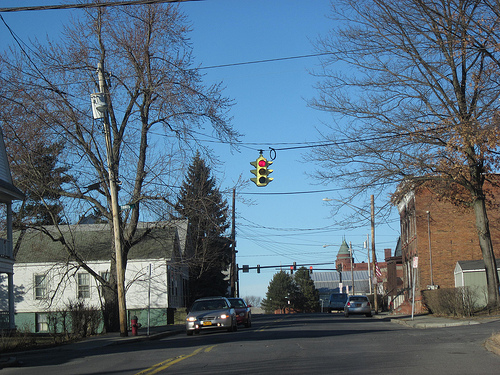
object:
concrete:
[0, 312, 497, 373]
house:
[0, 217, 189, 335]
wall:
[421, 191, 472, 244]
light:
[258, 159, 266, 167]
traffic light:
[290, 266, 295, 274]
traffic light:
[308, 266, 314, 274]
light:
[258, 176, 265, 183]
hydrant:
[131, 315, 142, 335]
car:
[185, 295, 237, 337]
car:
[226, 290, 253, 328]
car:
[343, 293, 374, 318]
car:
[328, 292, 349, 314]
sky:
[197, 15, 303, 48]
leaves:
[315, 40, 496, 188]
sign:
[412, 256, 418, 268]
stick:
[409, 270, 414, 320]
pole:
[101, 115, 131, 338]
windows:
[33, 272, 48, 301]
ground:
[391, 322, 429, 364]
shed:
[451, 255, 498, 317]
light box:
[249, 154, 274, 187]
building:
[453, 260, 500, 314]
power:
[85, 46, 136, 336]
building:
[0, 222, 185, 334]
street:
[1, 305, 498, 373]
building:
[389, 171, 499, 313]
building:
[336, 232, 388, 270]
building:
[308, 270, 378, 308]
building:
[0, 127, 17, 337]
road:
[1, 311, 498, 375]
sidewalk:
[92, 319, 182, 345]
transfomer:
[89, 88, 107, 119]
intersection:
[175, 292, 487, 371]